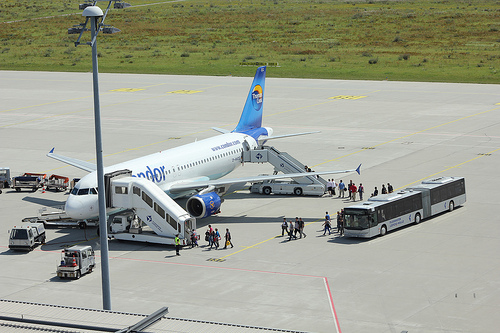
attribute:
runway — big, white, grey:
[5, 69, 499, 332]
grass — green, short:
[2, 0, 496, 86]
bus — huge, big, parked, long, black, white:
[339, 172, 472, 250]